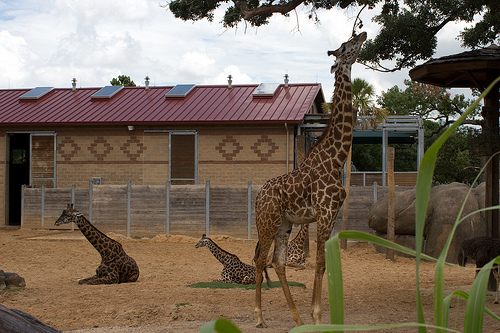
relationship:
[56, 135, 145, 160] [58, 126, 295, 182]
pattern on wall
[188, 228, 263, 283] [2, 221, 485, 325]
giraffe on ground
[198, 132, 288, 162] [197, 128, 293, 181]
pattern on wall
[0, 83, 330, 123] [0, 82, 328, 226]
roof on building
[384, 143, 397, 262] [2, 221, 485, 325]
post on ground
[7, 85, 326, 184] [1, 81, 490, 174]
building on background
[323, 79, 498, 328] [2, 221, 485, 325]
leaves on ground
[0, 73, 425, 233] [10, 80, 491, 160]
building on background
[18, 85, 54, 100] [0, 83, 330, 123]
panels on roof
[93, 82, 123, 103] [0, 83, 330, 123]
panels on roof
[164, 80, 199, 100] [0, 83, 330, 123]
panels on roof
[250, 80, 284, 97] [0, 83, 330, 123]
panels on roof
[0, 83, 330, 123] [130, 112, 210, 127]
roof has edge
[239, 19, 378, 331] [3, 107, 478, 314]
giraffe on pen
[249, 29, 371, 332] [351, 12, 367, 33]
giraffe eating leaf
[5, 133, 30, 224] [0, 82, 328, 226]
door of building